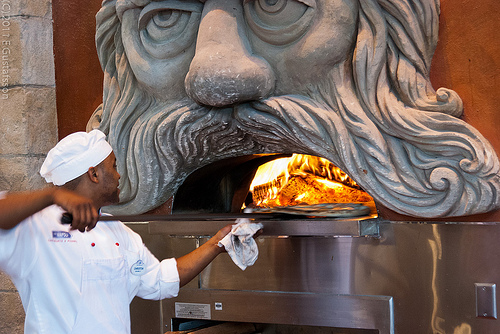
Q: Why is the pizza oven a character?
A: Prop.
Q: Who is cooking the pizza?
A: A chef.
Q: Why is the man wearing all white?
A: Uniform.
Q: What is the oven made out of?
A: Metal and stone.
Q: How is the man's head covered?
A: With a hat.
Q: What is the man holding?
A: An oven paddle.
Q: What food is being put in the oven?
A: A pizza.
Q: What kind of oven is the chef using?
A: A commercial oven.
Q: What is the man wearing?
A: A chef uniform.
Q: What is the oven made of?
A: Stainless steel.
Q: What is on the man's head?
A: A hat.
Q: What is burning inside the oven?
A: A fire.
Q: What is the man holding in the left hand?
A: A piece of cloth.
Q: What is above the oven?
A: A sculpture.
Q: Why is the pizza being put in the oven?
A: To be baked .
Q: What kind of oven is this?
A: A pizza oven.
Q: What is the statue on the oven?
A: A man with his mouth open.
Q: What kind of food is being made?
A: Pizza.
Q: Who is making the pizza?
A: A man in white.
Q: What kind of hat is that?
A: A chef hat.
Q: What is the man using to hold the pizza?
A: A large spatula.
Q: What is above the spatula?
A: The statue's nose.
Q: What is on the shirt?
A: A small blue name tag.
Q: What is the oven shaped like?
A: The mouth of a man.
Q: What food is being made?
A: Pizza.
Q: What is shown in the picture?
A: A pizza oven.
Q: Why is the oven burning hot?
A: It's being used.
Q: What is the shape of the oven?
A: A man's head.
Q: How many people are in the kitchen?
A: One.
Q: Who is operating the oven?
A: A chef.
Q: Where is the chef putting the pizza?
A: In the oven.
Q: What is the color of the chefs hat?
A: White.